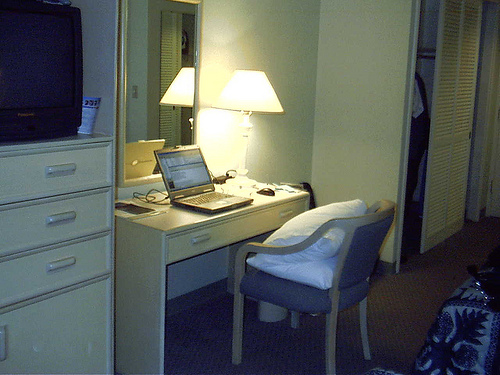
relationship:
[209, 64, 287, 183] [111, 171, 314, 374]
lamp on desk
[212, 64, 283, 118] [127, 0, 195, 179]
lampshade reflected in mirror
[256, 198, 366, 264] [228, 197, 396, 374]
pillow on chair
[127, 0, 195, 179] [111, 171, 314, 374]
mirror over desk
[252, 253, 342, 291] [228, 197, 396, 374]
pillow on chair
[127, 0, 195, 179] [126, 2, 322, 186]
mirror on wall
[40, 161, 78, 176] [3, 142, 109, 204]
drawer handle on drawer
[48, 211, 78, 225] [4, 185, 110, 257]
drawer handle on drawer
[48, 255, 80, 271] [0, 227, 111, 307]
drawer handle on drawer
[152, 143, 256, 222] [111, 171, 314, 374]
laptop on desk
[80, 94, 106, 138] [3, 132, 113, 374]
paper on dresser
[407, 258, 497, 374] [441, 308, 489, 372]
blanket with designs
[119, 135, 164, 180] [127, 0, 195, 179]
laptop reflection in mirror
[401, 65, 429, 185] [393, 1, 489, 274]
clothes in closet